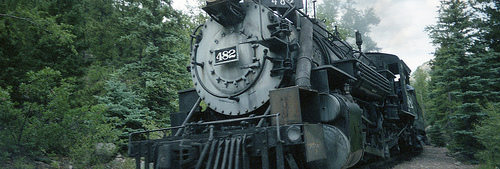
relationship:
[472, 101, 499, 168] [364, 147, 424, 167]
trees beside train track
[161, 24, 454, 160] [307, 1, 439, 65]
train emitting smoke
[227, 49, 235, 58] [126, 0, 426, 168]
number on train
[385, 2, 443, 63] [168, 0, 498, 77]
clouds in sky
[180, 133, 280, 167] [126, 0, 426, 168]
grate on train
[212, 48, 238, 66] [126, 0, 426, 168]
number on train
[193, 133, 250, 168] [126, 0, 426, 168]
grate on train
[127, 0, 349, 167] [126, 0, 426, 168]
train front on train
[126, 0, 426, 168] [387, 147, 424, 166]
train on train track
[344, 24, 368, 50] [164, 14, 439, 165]
whistle on train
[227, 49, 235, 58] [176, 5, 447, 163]
number on train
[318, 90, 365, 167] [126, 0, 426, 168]
engine on train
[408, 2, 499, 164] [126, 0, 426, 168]
trees growing beside train